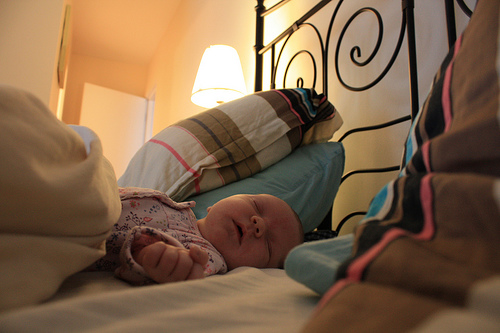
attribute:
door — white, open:
[76, 78, 157, 183]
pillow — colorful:
[114, 87, 343, 202]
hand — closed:
[134, 233, 217, 288]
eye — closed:
[260, 234, 280, 261]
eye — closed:
[248, 196, 264, 216]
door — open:
[82, 81, 149, 173]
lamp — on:
[169, 28, 267, 132]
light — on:
[157, 37, 256, 130]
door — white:
[77, 81, 159, 173]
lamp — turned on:
[189, 42, 249, 109]